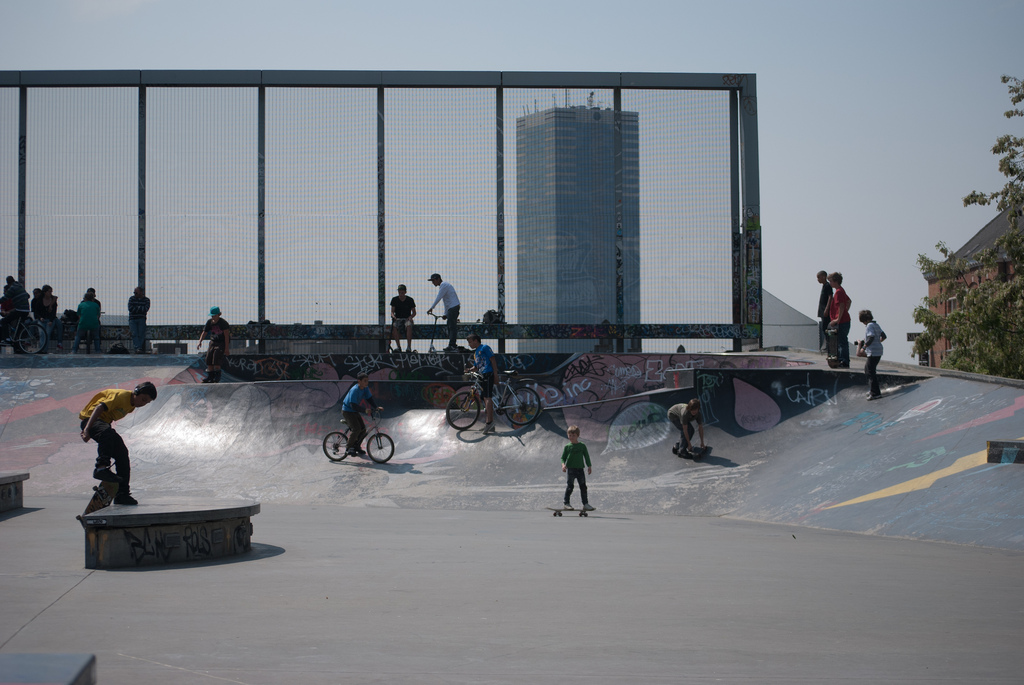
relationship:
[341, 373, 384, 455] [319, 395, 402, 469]
child on bike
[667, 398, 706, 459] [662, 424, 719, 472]
child on skateboard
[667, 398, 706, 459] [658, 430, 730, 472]
child on skateboard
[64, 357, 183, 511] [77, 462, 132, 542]
person on skateboard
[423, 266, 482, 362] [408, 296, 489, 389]
person on scooter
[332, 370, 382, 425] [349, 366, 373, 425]
child wearing shirt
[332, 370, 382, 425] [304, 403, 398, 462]
child on bike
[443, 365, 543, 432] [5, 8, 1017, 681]
bike at skatepark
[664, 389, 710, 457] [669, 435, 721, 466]
child doing tricks on skateboard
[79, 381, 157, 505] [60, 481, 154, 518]
person boy on h skateboard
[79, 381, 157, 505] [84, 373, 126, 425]
person boy wearing a yellow shirt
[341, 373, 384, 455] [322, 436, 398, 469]
child boy riding h bike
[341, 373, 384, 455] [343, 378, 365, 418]
child boy wearing a blue shirt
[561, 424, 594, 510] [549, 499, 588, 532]
boy boy on h skateboard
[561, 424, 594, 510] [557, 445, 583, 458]
boy boy wearing a green shirt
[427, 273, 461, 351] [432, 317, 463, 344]
person boy on a scooter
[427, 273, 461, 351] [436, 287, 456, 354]
person boy wearing a white shirt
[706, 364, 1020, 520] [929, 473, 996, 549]
graffiti written on ramp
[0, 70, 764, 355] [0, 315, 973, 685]
fence fence on side of skatepark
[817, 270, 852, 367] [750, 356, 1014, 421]
people boys standing on edge of park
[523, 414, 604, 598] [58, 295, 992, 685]
boy riding skateboard in middle of skatepark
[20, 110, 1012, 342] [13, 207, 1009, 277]
sky above everything